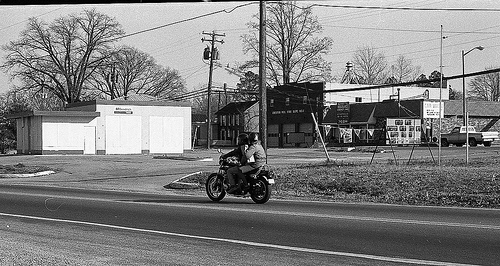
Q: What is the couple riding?
A: Motorcycle.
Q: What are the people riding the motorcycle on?
A: Road.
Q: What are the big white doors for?
A: Garage.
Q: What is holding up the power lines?
A: Posts.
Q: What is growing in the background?
A: Trees.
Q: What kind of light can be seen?
A: Street light.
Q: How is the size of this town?
A: Small.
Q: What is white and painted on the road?
A: Lines.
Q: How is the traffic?
A: Clear.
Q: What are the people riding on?
A: Motorcycle.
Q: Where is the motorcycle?
A: On the street.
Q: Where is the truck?
A: Next to a building.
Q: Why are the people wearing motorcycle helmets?
A: For protection.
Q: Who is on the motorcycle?
A: Two people.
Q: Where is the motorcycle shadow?
A: On the road.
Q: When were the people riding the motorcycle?
A: During daylight hours.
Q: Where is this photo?
A: Street.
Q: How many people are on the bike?
A: Two.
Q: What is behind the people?
A: Buildings.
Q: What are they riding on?
A: Motorcycle.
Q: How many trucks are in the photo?
A: One.